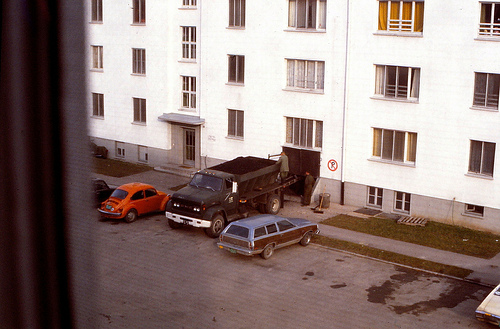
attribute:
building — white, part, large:
[84, 0, 498, 230]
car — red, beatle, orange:
[96, 176, 174, 228]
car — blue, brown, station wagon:
[214, 206, 323, 261]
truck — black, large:
[157, 151, 299, 221]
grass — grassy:
[328, 213, 499, 257]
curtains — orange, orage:
[378, 1, 428, 35]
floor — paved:
[99, 225, 476, 328]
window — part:
[277, 214, 298, 234]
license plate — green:
[227, 245, 238, 255]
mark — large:
[359, 259, 484, 318]